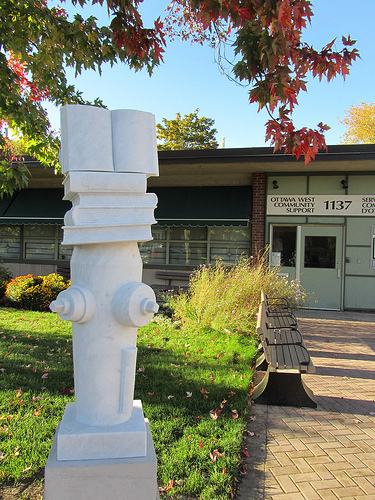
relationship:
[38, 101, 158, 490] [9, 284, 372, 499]
statue in front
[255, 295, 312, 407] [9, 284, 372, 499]
benches in front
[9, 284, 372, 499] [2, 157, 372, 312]
front of center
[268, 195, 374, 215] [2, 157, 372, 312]
sign on center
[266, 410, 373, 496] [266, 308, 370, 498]
pavers on sidewalk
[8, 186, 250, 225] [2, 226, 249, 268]
awning over windows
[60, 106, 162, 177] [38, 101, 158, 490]
book on statue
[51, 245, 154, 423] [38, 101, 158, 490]
hydrant on sculpture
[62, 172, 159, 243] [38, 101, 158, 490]
books on statue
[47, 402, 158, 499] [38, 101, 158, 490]
base of sculpture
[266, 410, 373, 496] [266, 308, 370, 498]
brick on walkway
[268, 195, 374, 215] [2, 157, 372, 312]
sign on building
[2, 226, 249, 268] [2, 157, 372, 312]
windows along building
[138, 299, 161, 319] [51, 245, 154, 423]
knob on hydrant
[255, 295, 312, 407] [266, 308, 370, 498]
bench on sidewalk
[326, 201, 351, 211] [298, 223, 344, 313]
1137 above door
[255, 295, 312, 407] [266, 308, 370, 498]
benches on sidewalk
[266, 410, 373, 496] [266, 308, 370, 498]
bricks on sidewalk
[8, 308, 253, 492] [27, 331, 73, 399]
grass has leaves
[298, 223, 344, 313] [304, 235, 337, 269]
door with window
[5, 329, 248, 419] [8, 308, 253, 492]
shadow on lawn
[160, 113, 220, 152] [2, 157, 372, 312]
tree behind building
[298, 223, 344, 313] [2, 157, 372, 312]
door on center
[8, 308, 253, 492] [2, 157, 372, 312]
grass by center